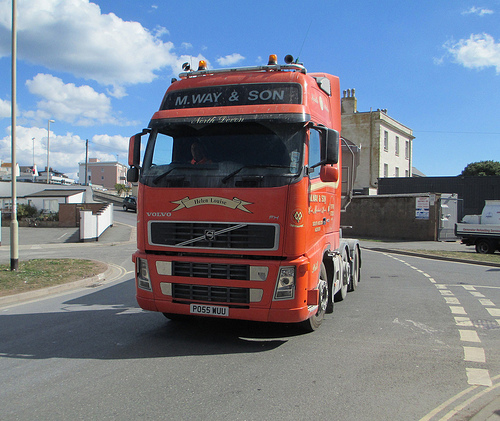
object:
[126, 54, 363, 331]
truck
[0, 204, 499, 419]
road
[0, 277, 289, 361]
shadow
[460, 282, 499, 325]
lines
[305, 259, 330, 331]
tires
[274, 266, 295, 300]
headlights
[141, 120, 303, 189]
windshield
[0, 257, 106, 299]
grass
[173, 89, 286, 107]
words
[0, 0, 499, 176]
sky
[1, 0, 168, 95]
clouds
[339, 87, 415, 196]
building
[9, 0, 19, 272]
pole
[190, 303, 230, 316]
license plate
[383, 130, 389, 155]
windows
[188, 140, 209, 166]
man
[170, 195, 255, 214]
logo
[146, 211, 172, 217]
volvo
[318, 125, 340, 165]
mirrors